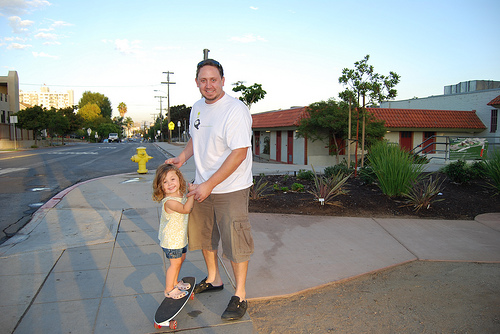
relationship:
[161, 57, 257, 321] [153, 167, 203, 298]
man holding onto girl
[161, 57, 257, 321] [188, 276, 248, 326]
man wears shoes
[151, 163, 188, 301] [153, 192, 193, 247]
girl wears shirt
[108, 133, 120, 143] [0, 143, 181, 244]
car on road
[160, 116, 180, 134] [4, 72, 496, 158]
sign in background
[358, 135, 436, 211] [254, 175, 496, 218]
plants growing in dirt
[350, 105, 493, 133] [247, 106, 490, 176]
roof of building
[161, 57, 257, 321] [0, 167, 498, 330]
man standing sidewalk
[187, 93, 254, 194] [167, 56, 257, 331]
shirt on man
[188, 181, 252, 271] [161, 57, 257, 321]
shorts on man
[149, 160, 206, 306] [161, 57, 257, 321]
girl standing next to man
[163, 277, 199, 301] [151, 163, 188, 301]
shoes on girl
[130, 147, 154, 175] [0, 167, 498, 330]
fire hydrant on sidewalk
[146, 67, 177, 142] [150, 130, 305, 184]
poles on sidewalk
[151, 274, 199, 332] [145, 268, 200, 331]
skateboard of skateboard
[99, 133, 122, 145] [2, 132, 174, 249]
car on road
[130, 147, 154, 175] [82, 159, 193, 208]
fire hydrant on corner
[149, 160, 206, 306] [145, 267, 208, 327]
girl standing on skateboard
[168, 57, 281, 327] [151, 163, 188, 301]
man holding up girl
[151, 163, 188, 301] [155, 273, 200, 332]
girl on skateboard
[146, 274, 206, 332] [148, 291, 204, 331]
skateboard with wheels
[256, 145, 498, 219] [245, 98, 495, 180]
landscaping in front of building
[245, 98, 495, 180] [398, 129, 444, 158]
building with doors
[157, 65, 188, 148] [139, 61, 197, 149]
pole in distance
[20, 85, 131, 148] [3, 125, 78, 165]
trees growing on sidewalk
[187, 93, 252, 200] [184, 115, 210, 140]
shirt with graphic